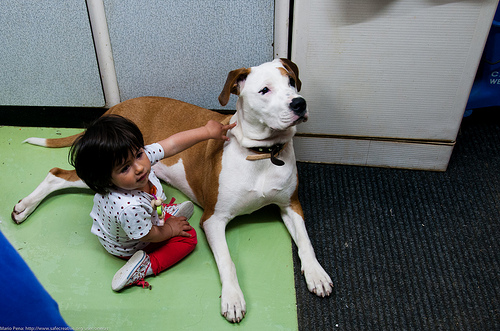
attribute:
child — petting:
[70, 127, 202, 283]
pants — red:
[140, 210, 203, 267]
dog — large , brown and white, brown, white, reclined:
[9, 55, 334, 322]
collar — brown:
[225, 137, 325, 169]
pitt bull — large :
[3, 41, 348, 329]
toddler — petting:
[68, 114, 235, 289]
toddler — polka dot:
[44, 95, 257, 311]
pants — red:
[137, 206, 212, 279]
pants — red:
[151, 199, 202, 270]